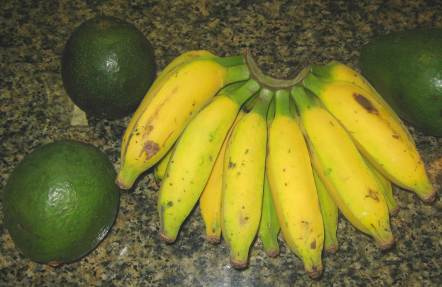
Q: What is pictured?
A: Bananas and avocados.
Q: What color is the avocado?
A: Green.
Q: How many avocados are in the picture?
A: Three.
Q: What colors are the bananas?
A: Yellow with brown.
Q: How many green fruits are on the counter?
A: 3.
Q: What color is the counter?
A: Brown and black.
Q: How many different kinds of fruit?
A: 2.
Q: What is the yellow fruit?
A: Bananas.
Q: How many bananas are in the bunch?
A: 11.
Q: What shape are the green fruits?
A: Round.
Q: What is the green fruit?
A: Avocados.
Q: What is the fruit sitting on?
A: Counter.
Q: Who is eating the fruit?
A: No one.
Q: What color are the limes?
A: Green.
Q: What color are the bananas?
A: Yellow.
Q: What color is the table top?
A: Gray.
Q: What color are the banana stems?
A: Green.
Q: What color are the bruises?
A: Brown.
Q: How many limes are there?
A: 3.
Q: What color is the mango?
A: Green.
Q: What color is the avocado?
A: Green.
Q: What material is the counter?
A: Marble.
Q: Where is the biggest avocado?
A: To the right of the bananas.